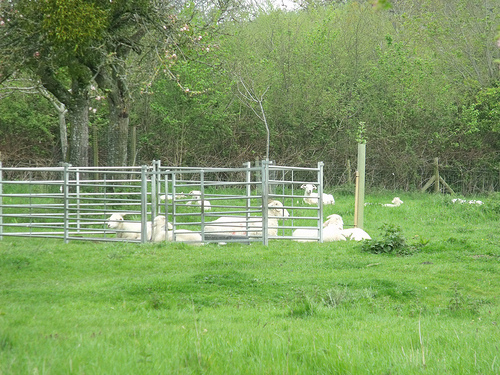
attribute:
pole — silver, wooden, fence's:
[132, 151, 157, 248]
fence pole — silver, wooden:
[87, 160, 154, 192]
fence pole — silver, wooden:
[348, 130, 383, 246]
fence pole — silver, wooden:
[265, 204, 322, 212]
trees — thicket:
[0, 0, 499, 182]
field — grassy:
[6, 180, 496, 373]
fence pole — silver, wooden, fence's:
[262, 162, 324, 176]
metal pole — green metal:
[355, 143, 365, 232]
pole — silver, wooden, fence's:
[265, 226, 319, 229]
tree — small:
[220, 45, 277, 151]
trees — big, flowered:
[0, 4, 170, 206]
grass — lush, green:
[9, 265, 454, 355]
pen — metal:
[4, 163, 330, 243]